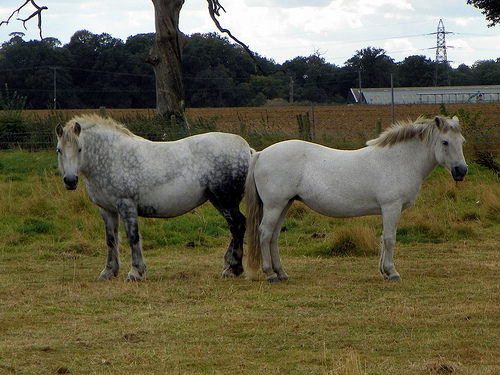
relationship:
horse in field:
[50, 112, 256, 284] [1, 144, 497, 371]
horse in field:
[334, 124, 453, 236] [183, 281, 347, 321]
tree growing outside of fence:
[143, 0, 188, 137] [2, 108, 498, 180]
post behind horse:
[308, 100, 315, 140] [238, 108, 473, 284]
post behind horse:
[308, 100, 315, 140] [50, 112, 256, 284]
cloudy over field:
[215, 7, 477, 72] [1, 108, 495, 373]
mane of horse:
[361, 107, 461, 146] [238, 108, 473, 284]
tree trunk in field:
[139, 0, 195, 158] [236, 282, 364, 333]